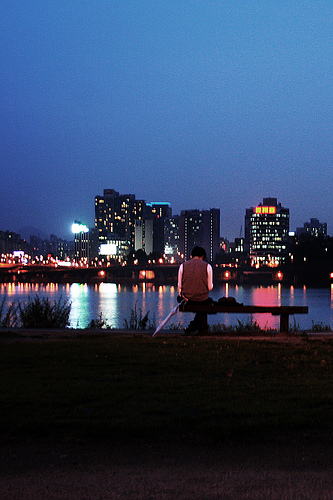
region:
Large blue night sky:
[6, 8, 321, 110]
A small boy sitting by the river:
[181, 247, 216, 304]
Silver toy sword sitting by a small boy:
[157, 297, 178, 333]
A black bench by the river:
[181, 299, 311, 321]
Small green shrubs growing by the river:
[4, 296, 74, 328]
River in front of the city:
[6, 278, 331, 324]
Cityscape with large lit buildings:
[20, 204, 316, 254]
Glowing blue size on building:
[70, 222, 96, 239]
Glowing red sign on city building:
[253, 202, 282, 217]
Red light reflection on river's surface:
[251, 282, 280, 332]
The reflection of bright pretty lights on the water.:
[5, 282, 128, 297]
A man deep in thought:
[177, 246, 211, 333]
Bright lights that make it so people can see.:
[69, 222, 88, 234]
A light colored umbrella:
[151, 299, 183, 336]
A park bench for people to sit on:
[180, 305, 308, 331]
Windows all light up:
[253, 205, 276, 213]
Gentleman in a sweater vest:
[176, 246, 211, 332]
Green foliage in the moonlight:
[2, 296, 71, 330]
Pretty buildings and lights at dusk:
[94, 188, 289, 266]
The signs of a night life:
[1, 250, 86, 267]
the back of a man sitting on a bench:
[178, 246, 212, 304]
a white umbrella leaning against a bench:
[151, 298, 180, 336]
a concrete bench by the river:
[177, 299, 308, 333]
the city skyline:
[0, 188, 329, 273]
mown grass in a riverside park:
[1, 329, 328, 498]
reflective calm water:
[1, 278, 328, 326]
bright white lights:
[71, 222, 87, 233]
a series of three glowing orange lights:
[254, 205, 274, 213]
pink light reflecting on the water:
[250, 285, 278, 330]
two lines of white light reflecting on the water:
[68, 281, 117, 326]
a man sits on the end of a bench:
[173, 240, 313, 335]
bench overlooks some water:
[3, 177, 332, 353]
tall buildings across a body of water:
[4, 177, 331, 326]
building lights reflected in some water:
[1, 267, 332, 304]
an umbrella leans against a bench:
[146, 293, 190, 336]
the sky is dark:
[1, 3, 332, 260]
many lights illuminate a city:
[0, 181, 332, 282]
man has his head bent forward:
[172, 244, 217, 337]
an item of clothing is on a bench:
[214, 293, 310, 317]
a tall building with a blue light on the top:
[143, 199, 172, 258]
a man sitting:
[176, 245, 217, 325]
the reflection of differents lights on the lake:
[8, 281, 164, 304]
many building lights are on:
[248, 213, 285, 261]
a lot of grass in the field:
[28, 358, 285, 442]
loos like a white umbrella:
[150, 301, 183, 339]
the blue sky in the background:
[9, 164, 324, 188]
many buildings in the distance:
[4, 191, 318, 258]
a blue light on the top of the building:
[145, 199, 169, 207]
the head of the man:
[189, 247, 204, 260]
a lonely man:
[178, 248, 212, 332]